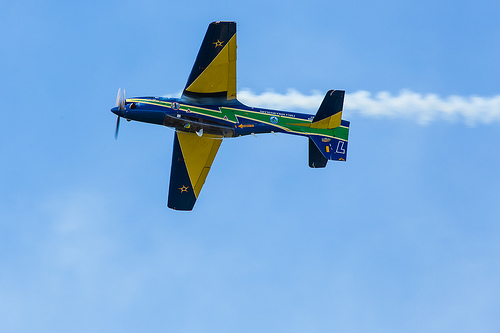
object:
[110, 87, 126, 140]
fan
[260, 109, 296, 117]
number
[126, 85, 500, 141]
stripe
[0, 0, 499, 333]
cloud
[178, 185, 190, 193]
star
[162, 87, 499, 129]
contrail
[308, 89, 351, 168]
tail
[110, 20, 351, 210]
airplane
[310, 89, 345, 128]
wing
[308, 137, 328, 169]
wing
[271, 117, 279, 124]
logo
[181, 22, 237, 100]
wing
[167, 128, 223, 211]
wing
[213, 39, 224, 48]
star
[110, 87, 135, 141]
nose